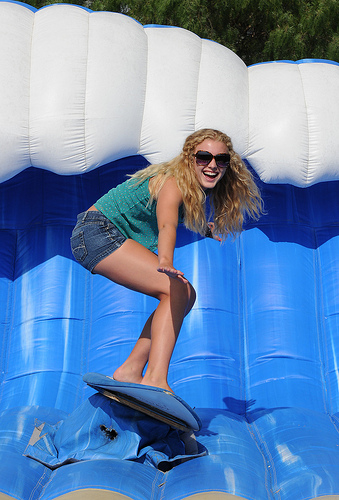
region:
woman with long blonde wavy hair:
[128, 118, 256, 222]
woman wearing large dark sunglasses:
[181, 127, 238, 202]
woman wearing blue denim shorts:
[63, 113, 231, 306]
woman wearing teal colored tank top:
[65, 127, 239, 281]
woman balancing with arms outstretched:
[150, 124, 239, 283]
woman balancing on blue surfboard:
[67, 116, 247, 433]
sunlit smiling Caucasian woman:
[183, 128, 231, 192]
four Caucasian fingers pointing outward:
[156, 264, 186, 276]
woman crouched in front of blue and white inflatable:
[67, 122, 257, 312]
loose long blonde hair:
[220, 178, 267, 236]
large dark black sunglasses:
[189, 148, 230, 169]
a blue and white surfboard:
[81, 372, 203, 433]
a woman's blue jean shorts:
[69, 206, 123, 279]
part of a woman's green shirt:
[92, 173, 167, 251]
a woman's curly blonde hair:
[124, 127, 267, 239]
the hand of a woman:
[155, 262, 187, 285]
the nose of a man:
[209, 157, 219, 170]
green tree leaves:
[130, 0, 334, 61]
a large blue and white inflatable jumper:
[0, 0, 338, 499]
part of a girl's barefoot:
[110, 369, 142, 384]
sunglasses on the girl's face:
[190, 151, 229, 167]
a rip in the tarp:
[100, 423, 116, 440]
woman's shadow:
[190, 393, 292, 435]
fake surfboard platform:
[82, 372, 202, 432]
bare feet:
[114, 368, 167, 390]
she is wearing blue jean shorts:
[69, 210, 124, 273]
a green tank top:
[92, 170, 163, 248]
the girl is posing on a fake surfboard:
[70, 127, 264, 430]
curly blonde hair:
[174, 129, 262, 237]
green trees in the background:
[37, 0, 337, 61]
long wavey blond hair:
[147, 118, 264, 240]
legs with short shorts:
[65, 201, 197, 399]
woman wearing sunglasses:
[78, 122, 244, 471]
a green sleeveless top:
[85, 159, 181, 255]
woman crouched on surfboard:
[58, 114, 255, 456]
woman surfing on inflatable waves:
[71, 118, 268, 451]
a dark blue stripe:
[242, 147, 338, 260]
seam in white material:
[70, 2, 110, 177]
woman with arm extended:
[63, 115, 247, 446]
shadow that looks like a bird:
[217, 389, 257, 415]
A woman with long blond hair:
[121, 127, 267, 243]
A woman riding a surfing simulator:
[67, 124, 265, 466]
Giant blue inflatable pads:
[201, 242, 335, 496]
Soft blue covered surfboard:
[82, 370, 202, 433]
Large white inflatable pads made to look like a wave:
[0, 0, 173, 183]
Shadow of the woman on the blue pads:
[194, 390, 291, 437]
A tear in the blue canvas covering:
[89, 420, 130, 461]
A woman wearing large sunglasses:
[182, 126, 233, 189]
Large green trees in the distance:
[71, 1, 335, 65]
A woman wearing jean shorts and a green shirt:
[68, 127, 267, 280]